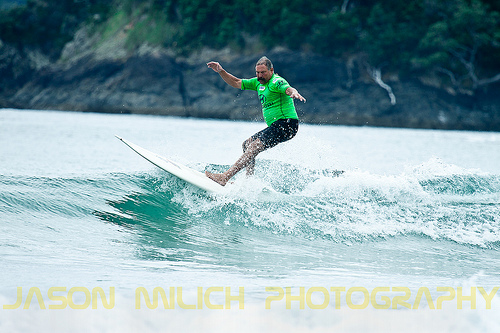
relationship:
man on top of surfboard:
[210, 54, 292, 182] [124, 138, 228, 206]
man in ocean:
[210, 54, 292, 182] [6, 123, 499, 315]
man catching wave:
[210, 54, 292, 182] [15, 171, 494, 224]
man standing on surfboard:
[210, 54, 292, 182] [124, 138, 228, 206]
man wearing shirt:
[210, 54, 292, 182] [239, 74, 299, 120]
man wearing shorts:
[210, 54, 292, 182] [250, 118, 301, 146]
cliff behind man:
[17, 37, 498, 125] [210, 54, 292, 182]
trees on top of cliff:
[8, 2, 495, 63] [17, 37, 498, 125]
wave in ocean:
[15, 171, 494, 224] [6, 123, 499, 315]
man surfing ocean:
[210, 54, 292, 182] [6, 123, 499, 315]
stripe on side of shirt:
[276, 94, 288, 120] [239, 74, 299, 120]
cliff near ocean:
[17, 37, 498, 125] [6, 123, 499, 315]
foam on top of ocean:
[218, 173, 496, 249] [6, 123, 499, 315]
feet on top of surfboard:
[200, 169, 250, 188] [124, 138, 228, 206]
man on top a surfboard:
[210, 54, 292, 182] [124, 138, 228, 206]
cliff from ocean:
[17, 37, 498, 125] [6, 123, 499, 315]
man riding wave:
[210, 54, 292, 182] [15, 171, 494, 224]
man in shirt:
[210, 54, 292, 182] [239, 74, 299, 120]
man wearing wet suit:
[210, 54, 292, 182] [244, 80, 299, 147]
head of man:
[255, 58, 275, 83] [210, 54, 292, 182]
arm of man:
[202, 59, 256, 92] [210, 54, 292, 182]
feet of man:
[202, 169, 230, 187] [210, 54, 292, 182]